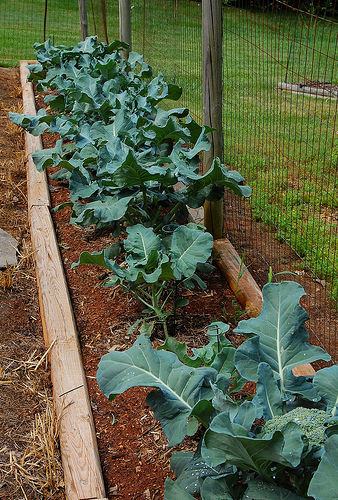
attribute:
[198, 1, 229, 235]
post — for fence, split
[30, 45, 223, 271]
flowers — green, big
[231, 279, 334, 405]
leaf — green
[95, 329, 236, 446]
leaf — green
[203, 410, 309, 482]
leaf — green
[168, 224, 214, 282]
leaf — green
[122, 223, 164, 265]
leaf — green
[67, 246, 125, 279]
leaf — green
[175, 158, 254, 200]
leaf — green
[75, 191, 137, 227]
leaf — green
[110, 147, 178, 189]
leaf — green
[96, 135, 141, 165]
leaf — green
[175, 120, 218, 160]
leaf — green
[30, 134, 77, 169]
leaf — green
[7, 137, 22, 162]
soil — brown and orange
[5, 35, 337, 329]
greens — green, small bunch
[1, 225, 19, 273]
rock — flat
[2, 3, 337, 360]
fence wire — horizontally and vertically.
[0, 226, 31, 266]
stone — partially visible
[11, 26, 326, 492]
plants — deep green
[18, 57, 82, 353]
wodden border — wooden, unpainted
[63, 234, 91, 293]
dirt — reddish brown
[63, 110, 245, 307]
flowers — big, green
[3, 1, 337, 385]
fence — crossed wire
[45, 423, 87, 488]
border — wooden 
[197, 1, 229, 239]
board — wooden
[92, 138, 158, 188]
flowers — big, green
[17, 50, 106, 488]
border — wood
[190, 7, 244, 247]
wooden post — gray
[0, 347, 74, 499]
dry grass — dry 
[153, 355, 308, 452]
flowers — big, green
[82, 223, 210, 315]
flower — big, green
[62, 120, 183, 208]
flower — green, big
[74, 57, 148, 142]
flower — green, big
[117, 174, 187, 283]
flower — big, green